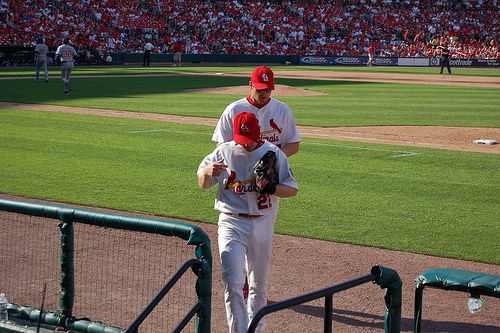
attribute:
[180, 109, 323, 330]
player — running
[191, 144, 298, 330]
uniform — grey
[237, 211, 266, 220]
belt — red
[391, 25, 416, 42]
people — crowd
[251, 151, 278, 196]
glove — black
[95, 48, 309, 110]
fence — green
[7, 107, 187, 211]
grass — green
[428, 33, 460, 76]
umpire — standing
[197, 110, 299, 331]
player — looking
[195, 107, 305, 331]
glove — black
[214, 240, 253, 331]
leg — lifted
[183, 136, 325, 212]
shirt — red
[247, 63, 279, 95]
cap — red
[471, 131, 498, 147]
base — white, first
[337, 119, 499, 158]
base — white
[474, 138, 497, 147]
base plate — white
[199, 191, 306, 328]
pants — white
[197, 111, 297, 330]
baseball player — entering